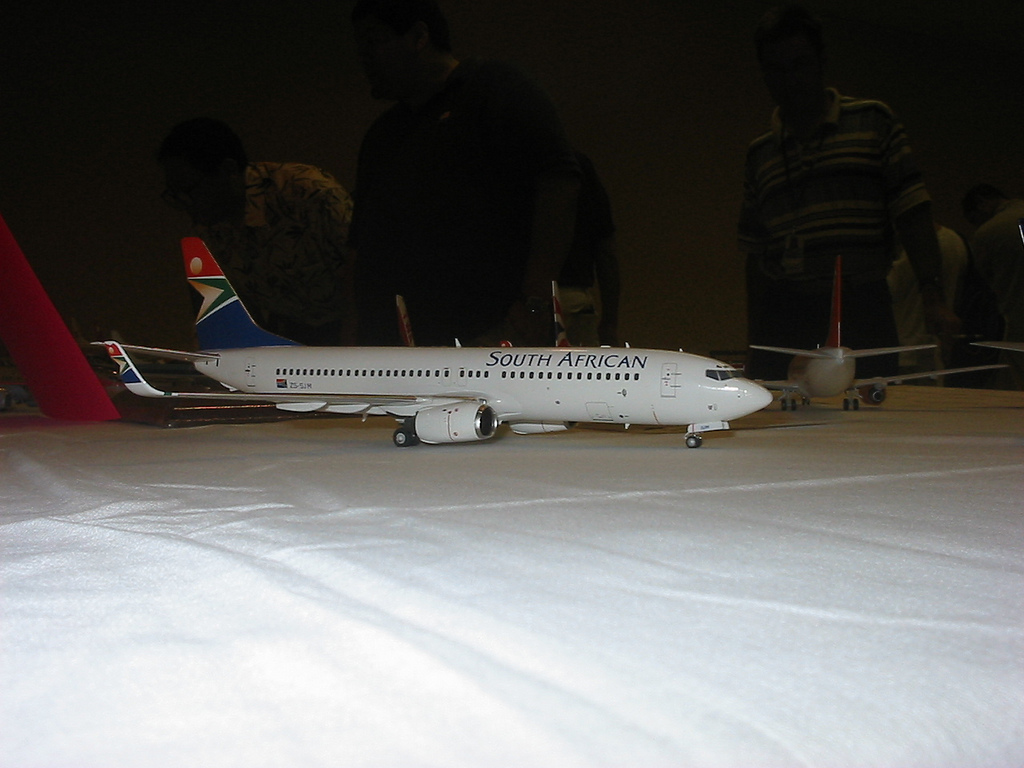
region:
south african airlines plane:
[89, 230, 778, 453]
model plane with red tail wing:
[744, 250, 1010, 415]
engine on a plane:
[412, 395, 498, 447]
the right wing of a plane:
[105, 337, 495, 410]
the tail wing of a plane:
[177, 240, 311, 349]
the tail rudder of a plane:
[89, 341, 220, 365]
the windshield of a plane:
[702, 367, 753, 381]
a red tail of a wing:
[825, 265, 846, 351]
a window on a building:
[610, 374, 617, 384]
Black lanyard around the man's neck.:
[775, 116, 815, 297]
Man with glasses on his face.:
[137, 104, 265, 241]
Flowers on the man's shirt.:
[245, 162, 329, 281]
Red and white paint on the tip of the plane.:
[175, 218, 218, 279]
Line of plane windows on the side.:
[260, 370, 678, 396]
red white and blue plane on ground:
[46, 256, 780, 460]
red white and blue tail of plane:
[157, 224, 259, 332]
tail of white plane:
[149, 230, 268, 347]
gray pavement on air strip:
[659, 574, 780, 701]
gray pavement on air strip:
[735, 564, 850, 676]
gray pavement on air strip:
[386, 552, 453, 595]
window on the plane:
[681, 363, 743, 390]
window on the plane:
[558, 369, 597, 392]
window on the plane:
[481, 369, 507, 383]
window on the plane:
[412, 358, 438, 379]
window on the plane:
[378, 366, 395, 383]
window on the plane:
[263, 373, 289, 374]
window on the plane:
[298, 356, 325, 385]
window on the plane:
[453, 369, 469, 385]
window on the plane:
[378, 361, 413, 377]